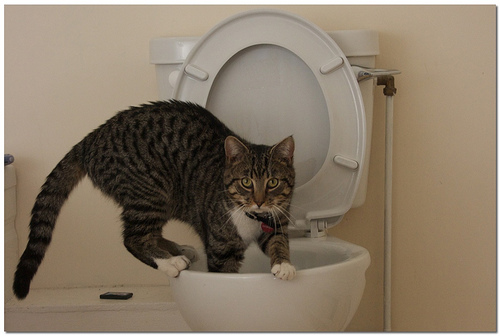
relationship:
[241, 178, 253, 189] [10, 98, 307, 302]
eye on cat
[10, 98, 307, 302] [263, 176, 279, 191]
cat has eye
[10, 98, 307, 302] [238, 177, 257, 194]
cat has eye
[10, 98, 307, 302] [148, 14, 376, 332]
cat standing on toilet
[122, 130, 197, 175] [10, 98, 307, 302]
stripes on cat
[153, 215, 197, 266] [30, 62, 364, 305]
leg on cat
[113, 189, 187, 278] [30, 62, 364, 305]
leg on cat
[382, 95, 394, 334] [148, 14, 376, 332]
pipe connected to toilet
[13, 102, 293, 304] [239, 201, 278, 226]
cat wearing collar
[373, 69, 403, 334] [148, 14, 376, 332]
pipe next to toilet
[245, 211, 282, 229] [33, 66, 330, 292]
collar on cat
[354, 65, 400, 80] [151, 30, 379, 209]
handle on tank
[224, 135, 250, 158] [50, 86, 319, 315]
ear of cat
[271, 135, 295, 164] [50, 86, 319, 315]
ear of cat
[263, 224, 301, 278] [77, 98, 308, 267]
leg of a cat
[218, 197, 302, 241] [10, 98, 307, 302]
whiskers on cat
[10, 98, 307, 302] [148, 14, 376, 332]
cat on toilet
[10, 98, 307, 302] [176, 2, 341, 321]
cat standing on toilet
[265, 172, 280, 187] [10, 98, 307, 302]
eye on cat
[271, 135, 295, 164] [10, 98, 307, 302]
ear of cat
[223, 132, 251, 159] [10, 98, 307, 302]
ear of cat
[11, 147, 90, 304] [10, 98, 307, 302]
tail of cat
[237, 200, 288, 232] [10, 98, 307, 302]
collar of cat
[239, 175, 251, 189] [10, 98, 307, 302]
eye of cat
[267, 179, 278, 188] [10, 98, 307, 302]
eye of cat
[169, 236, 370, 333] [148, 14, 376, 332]
toilet bowl of toilet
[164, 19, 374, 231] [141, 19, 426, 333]
seat of toilet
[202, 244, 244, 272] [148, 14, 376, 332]
leg in toilet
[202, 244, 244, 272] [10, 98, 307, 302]
leg of cat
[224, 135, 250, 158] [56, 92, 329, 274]
ear of cat